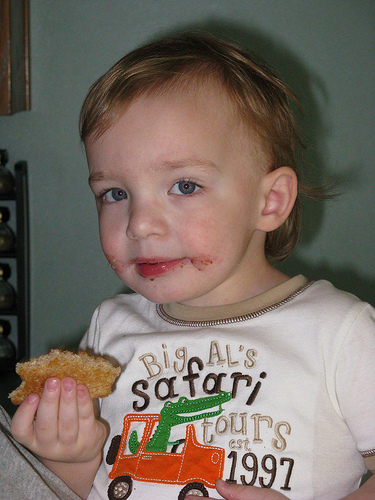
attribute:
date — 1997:
[226, 448, 297, 490]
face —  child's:
[60, 48, 259, 320]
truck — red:
[110, 384, 236, 498]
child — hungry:
[0, 16, 375, 498]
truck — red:
[100, 412, 228, 497]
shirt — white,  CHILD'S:
[74, 274, 374, 498]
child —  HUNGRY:
[79, 38, 323, 433]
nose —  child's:
[127, 206, 170, 232]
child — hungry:
[69, 28, 317, 489]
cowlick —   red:
[185, 32, 305, 115]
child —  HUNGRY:
[26, 20, 352, 360]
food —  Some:
[190, 256, 215, 272]